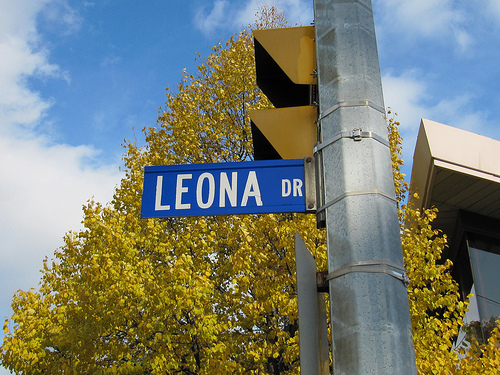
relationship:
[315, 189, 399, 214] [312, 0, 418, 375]
ring on pole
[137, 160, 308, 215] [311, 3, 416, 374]
sign on pole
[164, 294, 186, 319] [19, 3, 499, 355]
leaf on tree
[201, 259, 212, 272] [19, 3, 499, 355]
leaf on tree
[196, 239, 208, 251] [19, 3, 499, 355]
leaf on tree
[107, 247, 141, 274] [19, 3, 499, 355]
leaf on tree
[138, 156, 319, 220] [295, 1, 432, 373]
street sign fastened to pole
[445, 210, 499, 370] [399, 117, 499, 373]
windows are on tan building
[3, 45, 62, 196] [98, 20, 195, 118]
clouds are in sky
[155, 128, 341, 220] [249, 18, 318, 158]
street sign on crossing signal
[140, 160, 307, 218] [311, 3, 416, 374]
sign connected to pole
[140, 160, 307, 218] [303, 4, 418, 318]
sign on pole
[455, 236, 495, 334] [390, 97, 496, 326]
window on building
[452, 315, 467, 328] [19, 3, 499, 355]
yellow leaf on tree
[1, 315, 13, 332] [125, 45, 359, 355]
leaf on tree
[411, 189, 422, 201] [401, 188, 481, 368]
leaf on tree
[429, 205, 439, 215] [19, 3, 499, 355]
leaf on tree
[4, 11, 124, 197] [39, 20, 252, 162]
cloud in sky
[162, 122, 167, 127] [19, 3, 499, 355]
leaf on tree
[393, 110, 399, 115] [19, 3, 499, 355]
leaf on tree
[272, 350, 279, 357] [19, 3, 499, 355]
leaf on tree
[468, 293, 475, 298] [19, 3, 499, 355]
leaf on tree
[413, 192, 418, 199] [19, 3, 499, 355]
leaf on tree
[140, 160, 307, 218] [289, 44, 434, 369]
sign on a pole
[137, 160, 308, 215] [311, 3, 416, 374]
sign on a pole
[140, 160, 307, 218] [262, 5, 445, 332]
sign on a pole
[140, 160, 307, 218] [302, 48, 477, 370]
sign on pole